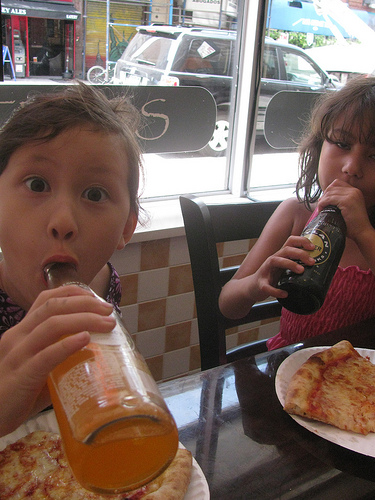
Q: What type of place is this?
A: It is a pizza shop.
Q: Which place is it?
A: It is a pizza shop.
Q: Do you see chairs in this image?
A: Yes, there is a chair.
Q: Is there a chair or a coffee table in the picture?
A: Yes, there is a chair.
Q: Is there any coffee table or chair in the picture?
A: Yes, there is a chair.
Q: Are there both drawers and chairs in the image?
A: No, there is a chair but no drawers.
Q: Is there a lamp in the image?
A: No, there are no lamps.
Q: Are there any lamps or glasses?
A: No, there are no lamps or glasses.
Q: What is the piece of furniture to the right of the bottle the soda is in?
A: The piece of furniture is a chair.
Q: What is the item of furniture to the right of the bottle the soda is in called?
A: The piece of furniture is a chair.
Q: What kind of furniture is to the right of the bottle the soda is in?
A: The piece of furniture is a chair.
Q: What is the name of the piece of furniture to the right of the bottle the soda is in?
A: The piece of furniture is a chair.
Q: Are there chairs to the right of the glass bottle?
A: Yes, there is a chair to the right of the bottle.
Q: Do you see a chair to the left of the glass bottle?
A: No, the chair is to the right of the bottle.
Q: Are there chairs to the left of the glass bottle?
A: No, the chair is to the right of the bottle.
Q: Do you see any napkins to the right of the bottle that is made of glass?
A: No, there is a chair to the right of the bottle.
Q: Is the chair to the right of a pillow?
A: No, the chair is to the right of a bottle.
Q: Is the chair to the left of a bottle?
A: No, the chair is to the right of a bottle.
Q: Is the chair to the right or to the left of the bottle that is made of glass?
A: The chair is to the right of the bottle.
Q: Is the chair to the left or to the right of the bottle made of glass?
A: The chair is to the right of the bottle.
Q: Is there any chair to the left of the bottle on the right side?
A: Yes, there is a chair to the left of the bottle.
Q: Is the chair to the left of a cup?
A: No, the chair is to the left of the bottle.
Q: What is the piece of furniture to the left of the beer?
A: The piece of furniture is a chair.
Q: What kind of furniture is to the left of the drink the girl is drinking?
A: The piece of furniture is a chair.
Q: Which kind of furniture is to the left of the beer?
A: The piece of furniture is a chair.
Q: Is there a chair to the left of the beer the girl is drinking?
A: Yes, there is a chair to the left of the beer.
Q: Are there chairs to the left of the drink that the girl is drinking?
A: Yes, there is a chair to the left of the beer.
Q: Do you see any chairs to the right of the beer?
A: No, the chair is to the left of the beer.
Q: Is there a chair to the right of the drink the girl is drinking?
A: No, the chair is to the left of the beer.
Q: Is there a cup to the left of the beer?
A: No, there is a chair to the left of the beer.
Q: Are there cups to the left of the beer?
A: No, there is a chair to the left of the beer.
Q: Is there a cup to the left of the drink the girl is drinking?
A: No, there is a chair to the left of the beer.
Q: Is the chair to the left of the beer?
A: Yes, the chair is to the left of the beer.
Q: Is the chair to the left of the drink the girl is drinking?
A: Yes, the chair is to the left of the beer.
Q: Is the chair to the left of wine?
A: No, the chair is to the left of the beer.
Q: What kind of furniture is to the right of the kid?
A: The piece of furniture is a chair.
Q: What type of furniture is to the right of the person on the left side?
A: The piece of furniture is a chair.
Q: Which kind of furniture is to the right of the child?
A: The piece of furniture is a chair.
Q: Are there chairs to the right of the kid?
A: Yes, there is a chair to the right of the kid.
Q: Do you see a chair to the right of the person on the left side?
A: Yes, there is a chair to the right of the kid.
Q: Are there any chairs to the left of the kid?
A: No, the chair is to the right of the kid.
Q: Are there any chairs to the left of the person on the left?
A: No, the chair is to the right of the kid.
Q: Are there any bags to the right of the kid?
A: No, there is a chair to the right of the kid.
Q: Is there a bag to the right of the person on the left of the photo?
A: No, there is a chair to the right of the kid.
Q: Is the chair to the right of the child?
A: Yes, the chair is to the right of the child.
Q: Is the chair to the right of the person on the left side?
A: Yes, the chair is to the right of the child.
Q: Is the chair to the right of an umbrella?
A: No, the chair is to the right of the child.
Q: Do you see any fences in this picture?
A: No, there are no fences.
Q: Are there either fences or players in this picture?
A: No, there are no fences or players.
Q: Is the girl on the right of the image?
A: Yes, the girl is on the right of the image.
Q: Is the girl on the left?
A: No, the girl is on the right of the image.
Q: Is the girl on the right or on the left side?
A: The girl is on the right of the image.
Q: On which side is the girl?
A: The girl is on the right of the image.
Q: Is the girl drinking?
A: Yes, the girl is drinking.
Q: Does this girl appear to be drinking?
A: Yes, the girl is drinking.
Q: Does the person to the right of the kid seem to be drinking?
A: Yes, the girl is drinking.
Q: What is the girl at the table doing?
A: The girl is drinking.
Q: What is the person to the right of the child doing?
A: The girl is drinking.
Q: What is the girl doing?
A: The girl is drinking.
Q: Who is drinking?
A: The girl is drinking.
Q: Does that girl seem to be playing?
A: No, the girl is drinking.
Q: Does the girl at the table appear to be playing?
A: No, the girl is drinking.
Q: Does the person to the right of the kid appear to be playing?
A: No, the girl is drinking.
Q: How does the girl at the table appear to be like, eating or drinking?
A: The girl is drinking.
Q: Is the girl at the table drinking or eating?
A: The girl is drinking.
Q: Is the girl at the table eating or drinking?
A: The girl is drinking.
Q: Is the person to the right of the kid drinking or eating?
A: The girl is drinking.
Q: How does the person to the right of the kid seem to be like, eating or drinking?
A: The girl is drinking.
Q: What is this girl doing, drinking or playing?
A: The girl is drinking.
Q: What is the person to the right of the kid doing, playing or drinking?
A: The girl is drinking.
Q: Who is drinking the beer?
A: The girl is drinking the beer.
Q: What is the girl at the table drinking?
A: The girl is drinking beer.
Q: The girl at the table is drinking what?
A: The girl is drinking beer.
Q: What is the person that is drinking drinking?
A: The girl is drinking beer.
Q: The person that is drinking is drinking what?
A: The girl is drinking beer.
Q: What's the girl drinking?
A: The girl is drinking beer.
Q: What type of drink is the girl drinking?
A: The girl is drinking beer.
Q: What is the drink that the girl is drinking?
A: The drink is beer.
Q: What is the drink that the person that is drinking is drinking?
A: The drink is beer.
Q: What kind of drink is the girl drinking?
A: The girl is drinking beer.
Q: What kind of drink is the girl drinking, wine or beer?
A: The girl is drinking beer.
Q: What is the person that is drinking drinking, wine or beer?
A: The girl is drinking beer.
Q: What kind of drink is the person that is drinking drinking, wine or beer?
A: The girl is drinking beer.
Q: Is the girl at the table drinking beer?
A: Yes, the girl is drinking beer.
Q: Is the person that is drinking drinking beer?
A: Yes, the girl is drinking beer.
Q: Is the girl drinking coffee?
A: No, the girl is drinking beer.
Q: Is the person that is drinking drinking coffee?
A: No, the girl is drinking beer.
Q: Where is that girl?
A: The girl is at the table.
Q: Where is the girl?
A: The girl is at the table.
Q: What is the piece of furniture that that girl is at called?
A: The piece of furniture is a table.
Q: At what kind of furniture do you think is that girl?
A: The girl is at the table.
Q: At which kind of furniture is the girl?
A: The girl is at the table.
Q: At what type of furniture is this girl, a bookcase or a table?
A: The girl is at a table.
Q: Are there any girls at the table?
A: Yes, there is a girl at the table.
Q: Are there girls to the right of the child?
A: Yes, there is a girl to the right of the child.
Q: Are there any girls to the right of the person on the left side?
A: Yes, there is a girl to the right of the child.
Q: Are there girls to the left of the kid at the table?
A: No, the girl is to the right of the child.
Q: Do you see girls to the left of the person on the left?
A: No, the girl is to the right of the child.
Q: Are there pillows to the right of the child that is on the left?
A: No, there is a girl to the right of the child.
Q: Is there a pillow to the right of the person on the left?
A: No, there is a girl to the right of the child.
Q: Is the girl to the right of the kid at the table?
A: Yes, the girl is to the right of the kid.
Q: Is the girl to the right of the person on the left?
A: Yes, the girl is to the right of the kid.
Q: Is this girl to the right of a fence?
A: No, the girl is to the right of the kid.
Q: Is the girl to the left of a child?
A: No, the girl is to the right of a child.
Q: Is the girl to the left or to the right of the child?
A: The girl is to the right of the child.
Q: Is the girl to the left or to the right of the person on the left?
A: The girl is to the right of the child.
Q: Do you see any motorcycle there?
A: No, there are no motorcycles.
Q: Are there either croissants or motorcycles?
A: No, there are no motorcycles or croissants.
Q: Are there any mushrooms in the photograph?
A: No, there are no mushrooms.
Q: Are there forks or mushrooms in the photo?
A: No, there are no mushrooms or forks.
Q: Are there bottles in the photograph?
A: Yes, there is a bottle.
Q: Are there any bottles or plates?
A: Yes, there is a bottle.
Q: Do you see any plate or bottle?
A: Yes, there is a bottle.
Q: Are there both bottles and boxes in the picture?
A: No, there is a bottle but no boxes.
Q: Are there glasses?
A: No, there are no glasses.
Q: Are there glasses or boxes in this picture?
A: No, there are no glasses or boxes.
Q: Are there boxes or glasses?
A: No, there are no glasses or boxes.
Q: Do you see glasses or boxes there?
A: No, there are no glasses or boxes.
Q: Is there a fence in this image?
A: No, there are no fences.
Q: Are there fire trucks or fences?
A: No, there are no fences or fire trucks.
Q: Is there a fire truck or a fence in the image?
A: No, there are no fences or fire trucks.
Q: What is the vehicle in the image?
A: The vehicle is a car.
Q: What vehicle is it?
A: The vehicle is a car.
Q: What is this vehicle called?
A: This is a car.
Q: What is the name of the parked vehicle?
A: The vehicle is a car.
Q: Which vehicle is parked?
A: The vehicle is a car.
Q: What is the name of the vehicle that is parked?
A: The vehicle is a car.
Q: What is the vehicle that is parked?
A: The vehicle is a car.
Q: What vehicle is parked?
A: The vehicle is a car.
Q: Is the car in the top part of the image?
A: Yes, the car is in the top of the image.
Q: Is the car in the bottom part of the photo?
A: No, the car is in the top of the image.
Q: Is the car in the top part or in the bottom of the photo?
A: The car is in the top of the image.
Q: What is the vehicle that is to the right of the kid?
A: The vehicle is a car.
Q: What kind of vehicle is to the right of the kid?
A: The vehicle is a car.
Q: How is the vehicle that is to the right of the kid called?
A: The vehicle is a car.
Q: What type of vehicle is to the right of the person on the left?
A: The vehicle is a car.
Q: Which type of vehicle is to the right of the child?
A: The vehicle is a car.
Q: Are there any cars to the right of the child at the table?
A: Yes, there is a car to the right of the child.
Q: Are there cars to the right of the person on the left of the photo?
A: Yes, there is a car to the right of the child.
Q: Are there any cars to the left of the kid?
A: No, the car is to the right of the kid.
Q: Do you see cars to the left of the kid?
A: No, the car is to the right of the kid.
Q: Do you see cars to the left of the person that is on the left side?
A: No, the car is to the right of the kid.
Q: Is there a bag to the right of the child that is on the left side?
A: No, there is a car to the right of the child.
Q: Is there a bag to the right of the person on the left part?
A: No, there is a car to the right of the child.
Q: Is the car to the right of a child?
A: Yes, the car is to the right of a child.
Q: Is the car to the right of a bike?
A: No, the car is to the right of a child.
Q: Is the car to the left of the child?
A: No, the car is to the right of the child.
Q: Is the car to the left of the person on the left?
A: No, the car is to the right of the child.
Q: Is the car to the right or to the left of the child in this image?
A: The car is to the right of the child.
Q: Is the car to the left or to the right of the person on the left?
A: The car is to the right of the child.